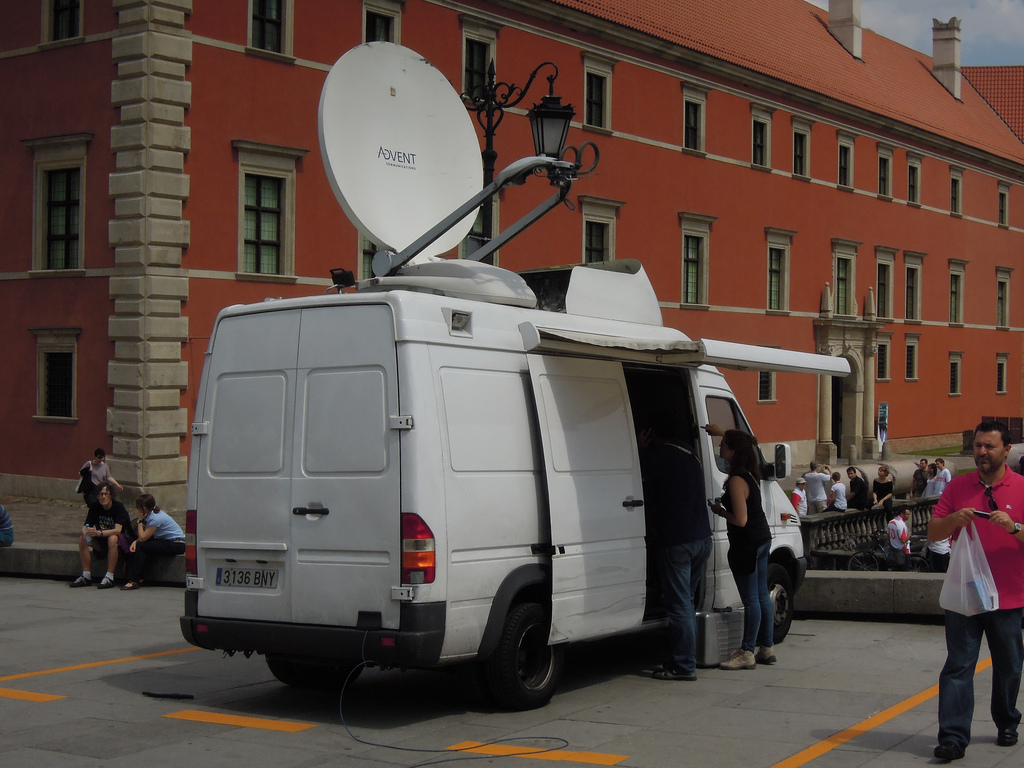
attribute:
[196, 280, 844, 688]
van — white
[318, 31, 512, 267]
satellite — white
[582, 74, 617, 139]
window — white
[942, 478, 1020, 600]
polo shirt — bright 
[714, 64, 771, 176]
window — white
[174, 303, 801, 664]
van — white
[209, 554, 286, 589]
licence plate — black , white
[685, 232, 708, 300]
window — white